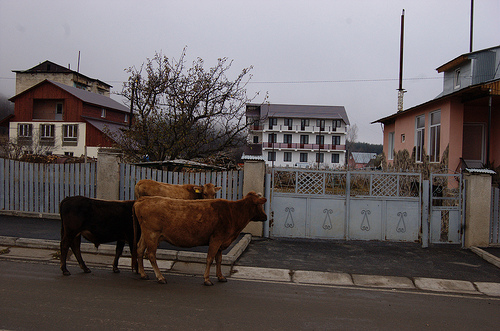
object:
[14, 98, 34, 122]
brick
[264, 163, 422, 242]
gate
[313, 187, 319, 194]
latticework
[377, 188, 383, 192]
latticework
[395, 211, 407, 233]
curlicues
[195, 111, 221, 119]
branches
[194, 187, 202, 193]
tag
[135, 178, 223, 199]
cow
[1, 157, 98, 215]
fencing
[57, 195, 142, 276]
cow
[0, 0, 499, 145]
sky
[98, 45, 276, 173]
trees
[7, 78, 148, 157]
house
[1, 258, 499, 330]
street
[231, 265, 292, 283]
square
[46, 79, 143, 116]
roof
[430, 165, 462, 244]
door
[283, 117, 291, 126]
window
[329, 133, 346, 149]
terraces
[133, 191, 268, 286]
cow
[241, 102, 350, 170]
white house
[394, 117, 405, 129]
pink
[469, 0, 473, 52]
poles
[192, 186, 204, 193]
ear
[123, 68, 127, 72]
leaves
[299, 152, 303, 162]
window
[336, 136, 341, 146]
window